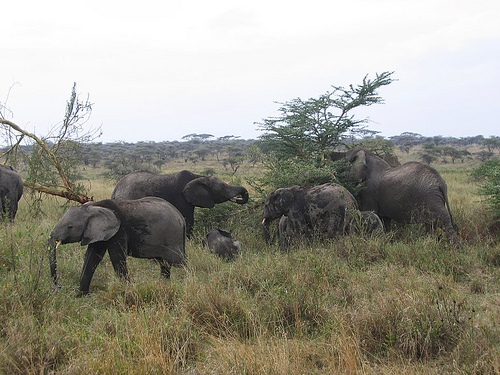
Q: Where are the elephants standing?
A: Tall grass.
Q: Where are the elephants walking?
A: Through the grass.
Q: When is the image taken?
A: Elephants are standing.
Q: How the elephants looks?
A: Large.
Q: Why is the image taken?
A: Remembrance.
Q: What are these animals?
A: Elephants.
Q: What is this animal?
A: Elephant in the wild.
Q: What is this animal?
A: A small elephant.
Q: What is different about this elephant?
A: Its coat is discolored.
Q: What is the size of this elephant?
A: Larger.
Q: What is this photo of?
A: A safari.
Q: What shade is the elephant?
A: Gray.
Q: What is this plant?
A: A tree.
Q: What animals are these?
A: Elephants.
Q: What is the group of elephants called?
A: A herd.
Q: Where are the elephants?
A: A field.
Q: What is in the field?
A: Tall grass.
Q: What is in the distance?
A: Trees.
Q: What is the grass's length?
A: Tall.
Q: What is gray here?
A: The elephants.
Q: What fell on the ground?
A: A tree.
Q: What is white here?
A: The sky.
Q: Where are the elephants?
A: In the bush.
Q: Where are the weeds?
A: On the ground.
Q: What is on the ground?
A: Grass.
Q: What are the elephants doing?
A: Eating.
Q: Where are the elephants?
A: In the savannah.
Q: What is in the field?
A: A herd of elephants.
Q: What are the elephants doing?
A: Grazing.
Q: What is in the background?
A: Sky.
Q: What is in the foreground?
A: Tall grass.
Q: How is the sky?
A: Cloudy.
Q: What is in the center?
A: Elephants.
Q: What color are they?
A: Gray.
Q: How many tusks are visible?
A: Three sets.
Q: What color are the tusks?
A: White.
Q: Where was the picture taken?
A: At a safari.